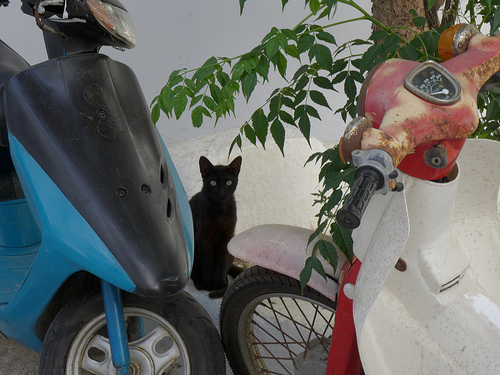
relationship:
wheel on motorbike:
[201, 262, 361, 373] [203, 15, 492, 359]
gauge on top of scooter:
[402, 58, 462, 105] [221, 21, 497, 373]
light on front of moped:
[85, 2, 140, 50] [0, 0, 229, 375]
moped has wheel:
[0, 0, 225, 373] [38, 282, 228, 373]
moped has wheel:
[218, 20, 498, 373] [220, 264, 340, 374]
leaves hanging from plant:
[162, 12, 332, 113] [145, 0, 499, 297]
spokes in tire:
[246, 294, 335, 373] [35, 289, 225, 373]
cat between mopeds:
[188, 155, 245, 299] [225, 19, 499, 374]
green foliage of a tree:
[149, 3, 498, 289] [130, 0, 499, 317]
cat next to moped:
[177, 157, 261, 271] [217, 23, 500, 374]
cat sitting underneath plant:
[188, 155, 245, 299] [170, 50, 292, 127]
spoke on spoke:
[264, 295, 299, 365] [317, 311, 335, 346]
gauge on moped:
[402, 58, 462, 105] [403, 55, 477, 106]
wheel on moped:
[218, 265, 363, 375] [52, 282, 220, 372]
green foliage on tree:
[268, 116, 285, 158] [151, 13, 484, 214]